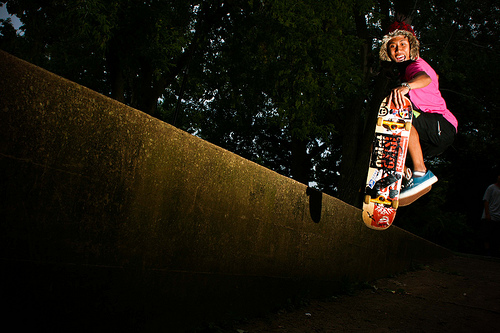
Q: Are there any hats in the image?
A: Yes, there is a hat.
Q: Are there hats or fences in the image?
A: Yes, there is a hat.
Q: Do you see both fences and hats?
A: No, there is a hat but no fences.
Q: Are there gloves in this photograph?
A: No, there are no gloves.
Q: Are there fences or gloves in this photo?
A: No, there are no gloves or fences.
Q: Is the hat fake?
A: Yes, the hat is fake.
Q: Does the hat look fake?
A: Yes, the hat is fake.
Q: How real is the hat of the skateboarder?
A: The hat is fake.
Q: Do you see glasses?
A: No, there are no glasses.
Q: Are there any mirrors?
A: No, there are no mirrors.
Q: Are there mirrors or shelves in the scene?
A: No, there are no mirrors or shelves.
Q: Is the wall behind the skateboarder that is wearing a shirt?
A: Yes, the wall is behind the skateboarder.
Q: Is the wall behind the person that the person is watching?
A: Yes, the wall is behind the skateboarder.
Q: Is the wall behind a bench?
A: No, the wall is behind the skateboarder.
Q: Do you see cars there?
A: No, there are no cars.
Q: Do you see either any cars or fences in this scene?
A: No, there are no cars or fences.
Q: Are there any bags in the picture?
A: No, there are no bags.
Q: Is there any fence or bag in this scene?
A: No, there are no bags or fences.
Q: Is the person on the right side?
A: Yes, the person is on the right of the image.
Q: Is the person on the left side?
A: No, the person is on the right of the image.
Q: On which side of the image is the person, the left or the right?
A: The person is on the right of the image.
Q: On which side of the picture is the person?
A: The person is on the right of the image.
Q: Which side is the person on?
A: The person is on the right of the image.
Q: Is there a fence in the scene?
A: No, there are no fences.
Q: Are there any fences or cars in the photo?
A: No, there are no fences or cars.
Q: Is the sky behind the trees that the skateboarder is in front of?
A: Yes, the sky is behind the trees.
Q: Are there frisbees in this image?
A: No, there are no frisbees.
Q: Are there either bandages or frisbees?
A: No, there are no frisbees or bandages.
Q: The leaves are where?
A: The leaves are on the ground.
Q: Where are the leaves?
A: The leaves are on the ground.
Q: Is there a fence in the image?
A: No, there are no fences.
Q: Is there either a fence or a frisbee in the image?
A: No, there are no fences or frisbees.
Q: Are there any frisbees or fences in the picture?
A: No, there are no fences or frisbees.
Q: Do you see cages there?
A: No, there are no cages.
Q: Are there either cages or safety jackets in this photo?
A: No, there are no cages or safety jackets.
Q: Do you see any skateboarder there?
A: Yes, there is a skateboarder.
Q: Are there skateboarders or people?
A: Yes, there is a skateboarder.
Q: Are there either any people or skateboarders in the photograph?
A: Yes, there is a skateboarder.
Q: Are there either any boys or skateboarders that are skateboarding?
A: Yes, the skateboarder is skateboarding.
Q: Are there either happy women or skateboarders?
A: Yes, there is a happy skateboarder.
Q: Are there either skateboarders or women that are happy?
A: Yes, the skateboarder is happy.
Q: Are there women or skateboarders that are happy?
A: Yes, the skateboarder is happy.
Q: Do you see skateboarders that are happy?
A: Yes, there is a happy skateboarder.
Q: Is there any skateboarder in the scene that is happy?
A: Yes, there is a skateboarder that is happy.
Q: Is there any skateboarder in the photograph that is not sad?
A: Yes, there is a happy skateboarder.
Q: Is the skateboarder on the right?
A: Yes, the skateboarder is on the right of the image.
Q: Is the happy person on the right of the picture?
A: Yes, the skateboarder is on the right of the image.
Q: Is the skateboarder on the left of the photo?
A: No, the skateboarder is on the right of the image.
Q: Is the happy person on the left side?
A: No, the skateboarder is on the right of the image.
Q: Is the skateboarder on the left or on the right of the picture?
A: The skateboarder is on the right of the image.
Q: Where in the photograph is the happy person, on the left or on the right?
A: The skateboarder is on the right of the image.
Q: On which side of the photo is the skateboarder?
A: The skateboarder is on the right of the image.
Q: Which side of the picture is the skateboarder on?
A: The skateboarder is on the right of the image.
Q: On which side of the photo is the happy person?
A: The skateboarder is on the right of the image.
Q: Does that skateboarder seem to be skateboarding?
A: Yes, the skateboarder is skateboarding.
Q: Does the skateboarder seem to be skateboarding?
A: Yes, the skateboarder is skateboarding.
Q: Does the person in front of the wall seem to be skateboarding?
A: Yes, the skateboarder is skateboarding.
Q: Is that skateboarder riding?
A: No, the skateboarder is skateboarding.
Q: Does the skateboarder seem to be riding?
A: No, the skateboarder is skateboarding.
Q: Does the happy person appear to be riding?
A: No, the skateboarder is skateboarding.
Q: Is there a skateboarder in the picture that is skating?
A: No, there is a skateboarder but he is skateboarding.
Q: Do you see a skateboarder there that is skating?
A: No, there is a skateboarder but he is skateboarding.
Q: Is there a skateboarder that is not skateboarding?
A: No, there is a skateboarder but he is skateboarding.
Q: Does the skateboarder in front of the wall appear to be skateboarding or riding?
A: The skateboarder is skateboarding.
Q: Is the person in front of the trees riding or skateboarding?
A: The skateboarder is skateboarding.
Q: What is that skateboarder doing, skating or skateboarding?
A: The skateboarder is skateboarding.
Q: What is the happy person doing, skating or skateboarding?
A: The skateboarder is skateboarding.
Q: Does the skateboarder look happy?
A: Yes, the skateboarder is happy.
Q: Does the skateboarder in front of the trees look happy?
A: Yes, the skateboarder is happy.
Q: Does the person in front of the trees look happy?
A: Yes, the skateboarder is happy.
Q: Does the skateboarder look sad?
A: No, the skateboarder is happy.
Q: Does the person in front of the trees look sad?
A: No, the skateboarder is happy.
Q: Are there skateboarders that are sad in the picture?
A: No, there is a skateboarder but he is happy.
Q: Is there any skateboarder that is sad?
A: No, there is a skateboarder but he is happy.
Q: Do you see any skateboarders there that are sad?
A: No, there is a skateboarder but he is happy.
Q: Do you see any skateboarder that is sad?
A: No, there is a skateboarder but he is happy.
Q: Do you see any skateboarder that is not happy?
A: No, there is a skateboarder but he is happy.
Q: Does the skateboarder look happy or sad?
A: The skateboarder is happy.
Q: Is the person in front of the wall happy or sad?
A: The skateboarder is happy.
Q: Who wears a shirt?
A: The skateboarder wears a shirt.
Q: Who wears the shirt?
A: The skateboarder wears a shirt.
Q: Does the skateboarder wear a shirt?
A: Yes, the skateboarder wears a shirt.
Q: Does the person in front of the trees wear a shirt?
A: Yes, the skateboarder wears a shirt.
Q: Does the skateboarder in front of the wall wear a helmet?
A: No, the skateboarder wears a shirt.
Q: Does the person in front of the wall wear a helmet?
A: No, the skateboarder wears a shirt.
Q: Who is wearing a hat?
A: The skateboarder is wearing a hat.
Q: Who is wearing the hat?
A: The skateboarder is wearing a hat.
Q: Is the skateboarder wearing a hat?
A: Yes, the skateboarder is wearing a hat.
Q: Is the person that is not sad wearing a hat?
A: Yes, the skateboarder is wearing a hat.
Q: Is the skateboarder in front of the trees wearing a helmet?
A: No, the skateboarder is wearing a hat.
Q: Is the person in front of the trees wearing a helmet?
A: No, the skateboarder is wearing a hat.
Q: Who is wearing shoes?
A: The skateboarder is wearing shoes.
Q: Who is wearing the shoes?
A: The skateboarder is wearing shoes.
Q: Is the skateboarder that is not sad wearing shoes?
A: Yes, the skateboarder is wearing shoes.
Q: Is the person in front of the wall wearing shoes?
A: Yes, the skateboarder is wearing shoes.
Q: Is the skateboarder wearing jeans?
A: No, the skateboarder is wearing shoes.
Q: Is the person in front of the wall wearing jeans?
A: No, the skateboarder is wearing shoes.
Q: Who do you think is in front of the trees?
A: The skateboarder is in front of the trees.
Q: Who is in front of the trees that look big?
A: The skateboarder is in front of the trees.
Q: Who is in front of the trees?
A: The skateboarder is in front of the trees.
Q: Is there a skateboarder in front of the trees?
A: Yes, there is a skateboarder in front of the trees.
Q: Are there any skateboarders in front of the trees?
A: Yes, there is a skateboarder in front of the trees.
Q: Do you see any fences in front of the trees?
A: No, there is a skateboarder in front of the trees.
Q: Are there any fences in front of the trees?
A: No, there is a skateboarder in front of the trees.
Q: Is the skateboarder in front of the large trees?
A: Yes, the skateboarder is in front of the trees.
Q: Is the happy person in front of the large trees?
A: Yes, the skateboarder is in front of the trees.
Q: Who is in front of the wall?
A: The skateboarder is in front of the wall.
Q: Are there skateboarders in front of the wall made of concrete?
A: Yes, there is a skateboarder in front of the wall.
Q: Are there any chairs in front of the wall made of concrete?
A: No, there is a skateboarder in front of the wall.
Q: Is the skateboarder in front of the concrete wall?
A: Yes, the skateboarder is in front of the wall.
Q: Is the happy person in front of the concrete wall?
A: Yes, the skateboarder is in front of the wall.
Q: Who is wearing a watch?
A: The skateboarder is wearing a watch.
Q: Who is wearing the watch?
A: The skateboarder is wearing a watch.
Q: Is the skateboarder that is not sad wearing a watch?
A: Yes, the skateboarder is wearing a watch.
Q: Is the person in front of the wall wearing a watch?
A: Yes, the skateboarder is wearing a watch.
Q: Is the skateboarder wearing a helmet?
A: No, the skateboarder is wearing a watch.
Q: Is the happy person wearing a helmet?
A: No, the skateboarder is wearing a watch.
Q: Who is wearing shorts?
A: The skateboarder is wearing shorts.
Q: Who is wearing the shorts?
A: The skateboarder is wearing shorts.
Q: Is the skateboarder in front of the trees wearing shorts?
A: Yes, the skateboarder is wearing shorts.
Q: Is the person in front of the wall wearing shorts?
A: Yes, the skateboarder is wearing shorts.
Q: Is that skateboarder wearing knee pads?
A: No, the skateboarder is wearing shorts.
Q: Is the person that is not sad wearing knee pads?
A: No, the skateboarder is wearing shorts.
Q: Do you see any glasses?
A: No, there are no glasses.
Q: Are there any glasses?
A: No, there are no glasses.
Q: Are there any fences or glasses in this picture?
A: No, there are no glasses or fences.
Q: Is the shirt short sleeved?
A: Yes, the shirt is short sleeved.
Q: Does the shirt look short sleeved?
A: Yes, the shirt is short sleeved.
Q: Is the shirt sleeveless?
A: No, the shirt is short sleeved.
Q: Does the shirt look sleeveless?
A: No, the shirt is short sleeved.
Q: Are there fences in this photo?
A: No, there are no fences.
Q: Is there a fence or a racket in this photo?
A: No, there are no fences or rackets.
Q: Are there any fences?
A: No, there are no fences.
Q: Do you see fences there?
A: No, there are no fences.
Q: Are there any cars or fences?
A: No, there are no fences or cars.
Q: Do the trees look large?
A: Yes, the trees are large.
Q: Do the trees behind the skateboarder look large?
A: Yes, the trees are large.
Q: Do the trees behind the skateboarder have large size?
A: Yes, the trees are large.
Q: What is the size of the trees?
A: The trees are large.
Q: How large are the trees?
A: The trees are large.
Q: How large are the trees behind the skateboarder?
A: The trees are large.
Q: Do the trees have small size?
A: No, the trees are large.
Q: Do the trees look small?
A: No, the trees are large.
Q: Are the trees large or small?
A: The trees are large.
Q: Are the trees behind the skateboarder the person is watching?
A: Yes, the trees are behind the skateboarder.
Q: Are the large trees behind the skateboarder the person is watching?
A: Yes, the trees are behind the skateboarder.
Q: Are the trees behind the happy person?
A: Yes, the trees are behind the skateboarder.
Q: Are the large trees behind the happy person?
A: Yes, the trees are behind the skateboarder.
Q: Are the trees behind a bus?
A: No, the trees are behind the skateboarder.